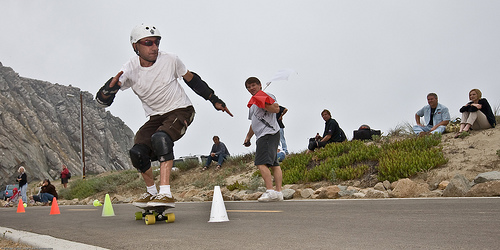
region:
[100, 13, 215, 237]
man skateboarding down street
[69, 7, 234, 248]
skateboarding down a hill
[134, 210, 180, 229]
yellow wheels on skateboard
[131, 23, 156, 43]
white helmet on head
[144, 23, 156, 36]
holes on front of helmet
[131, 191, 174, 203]
brown and white shoes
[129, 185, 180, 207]
medium length white socks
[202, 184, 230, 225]
white cone on the street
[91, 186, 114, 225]
yellow cone on street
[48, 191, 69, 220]
orange cone on street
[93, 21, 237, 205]
a person on a skateboard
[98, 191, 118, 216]
a yellow plastic cone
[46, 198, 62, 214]
an orange plastic cone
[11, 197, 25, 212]
an orange plastic cone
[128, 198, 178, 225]
A skateboard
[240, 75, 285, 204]
A person in a white shirt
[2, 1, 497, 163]
a grey, cloudy sky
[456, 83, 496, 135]
a woman in a black shirt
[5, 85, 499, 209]
some people sitting on a hill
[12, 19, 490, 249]
Skateboarders and spectators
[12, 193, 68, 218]
Red cones on paved street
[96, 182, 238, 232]
Yellow and white cones on paved street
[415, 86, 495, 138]
Spectators sitting on dirt hill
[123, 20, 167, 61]
Man wearing white helmet and sunglasses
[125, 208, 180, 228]
Skateboard wheels hugging city street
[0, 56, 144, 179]
Rocky hills in backdrop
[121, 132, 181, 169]
Two black knee pads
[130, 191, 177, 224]
Brown tennis shoes planted on skateboard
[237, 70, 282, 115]
Man holding red flag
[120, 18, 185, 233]
a man riding a skateboard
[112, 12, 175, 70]
a man wearing a white helmet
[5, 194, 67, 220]
two small orange cones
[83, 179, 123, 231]
two light green cones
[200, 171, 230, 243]
a small white cone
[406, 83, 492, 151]
two people sitting on the ground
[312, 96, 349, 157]
a man wearing black clothing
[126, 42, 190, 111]
a man wearing a white shirt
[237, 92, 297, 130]
a man holding a orange flag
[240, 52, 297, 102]
a man holding a white flag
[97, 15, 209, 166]
this is a man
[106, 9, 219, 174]
the man is skating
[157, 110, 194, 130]
this is the short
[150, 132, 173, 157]
he is wearing knee cap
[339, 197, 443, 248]
this is the road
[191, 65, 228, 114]
this is the hand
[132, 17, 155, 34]
this is a helmet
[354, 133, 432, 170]
these are the grass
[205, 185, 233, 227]
this is a reflector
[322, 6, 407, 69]
this is the sky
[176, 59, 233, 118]
arm of a man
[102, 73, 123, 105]
arm of a man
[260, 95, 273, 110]
arm of a man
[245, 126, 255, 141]
arm of a man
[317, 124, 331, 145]
arm of a man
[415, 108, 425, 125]
arm of a man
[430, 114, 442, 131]
arm of a man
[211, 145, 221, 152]
arm of a man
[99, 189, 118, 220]
the cone is yellow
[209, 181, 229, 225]
the cone is white